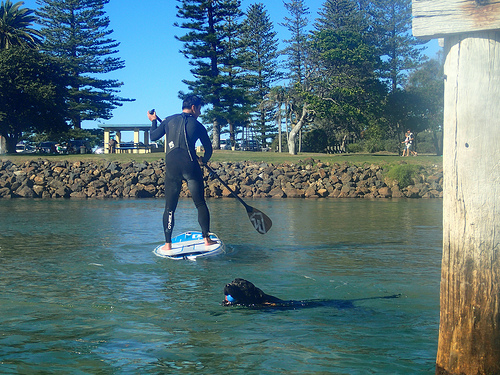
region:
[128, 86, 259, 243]
this is a person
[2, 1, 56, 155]
this is a tree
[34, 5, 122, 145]
this is a tree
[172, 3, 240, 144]
this is a tree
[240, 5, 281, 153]
this is a tree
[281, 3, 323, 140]
this is a tree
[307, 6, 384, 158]
this is a tree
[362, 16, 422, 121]
this is a tree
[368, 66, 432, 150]
this is a tree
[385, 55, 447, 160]
this is a tree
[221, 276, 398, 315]
A dog in the water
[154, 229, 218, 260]
A board on the water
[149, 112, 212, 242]
The man is wearing a wetsuit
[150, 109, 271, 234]
A paddle in the man's hands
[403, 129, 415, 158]
People walking on the grass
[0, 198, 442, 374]
A body of water beneath the board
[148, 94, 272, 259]
A man paddling on a board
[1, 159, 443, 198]
Rocks on the shore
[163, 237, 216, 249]
The man is not wearing shoes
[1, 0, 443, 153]
Trees near the water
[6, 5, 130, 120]
Green trees in the background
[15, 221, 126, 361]
Large body of water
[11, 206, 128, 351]
Body of blue water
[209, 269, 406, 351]
Dog in the water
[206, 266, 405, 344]
Black dog in the water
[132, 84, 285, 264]
A man on a paddle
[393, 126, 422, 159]
Two people in the background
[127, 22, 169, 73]
Blue skies in the background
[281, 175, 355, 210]
Rocks near the water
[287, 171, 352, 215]
Rocks near blue water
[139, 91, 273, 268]
Man wearing a wetsuit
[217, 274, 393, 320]
Dog swimming in water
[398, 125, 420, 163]
People walking in the distance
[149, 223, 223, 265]
Blue and white surfboard in water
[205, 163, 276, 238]
Black paddle with blue image on it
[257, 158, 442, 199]
Rock wall on side of lake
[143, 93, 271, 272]
Man standing on a surfboard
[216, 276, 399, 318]
Dog holding blue ball in its mouth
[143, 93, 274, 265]
Man using a paddle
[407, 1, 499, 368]
Large wooden pole in water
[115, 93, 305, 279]
man standing on the board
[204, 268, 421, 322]
black dog in the water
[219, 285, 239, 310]
dog's mouth is open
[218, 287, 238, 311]
blue ball in the mouth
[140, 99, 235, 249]
man is wearing a black wetsuit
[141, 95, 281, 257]
man is holding a black paddle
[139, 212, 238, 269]
blue and white board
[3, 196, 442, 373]
small body of water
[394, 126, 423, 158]
two people walking on the shore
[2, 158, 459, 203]
piles of rocks along the water's edge